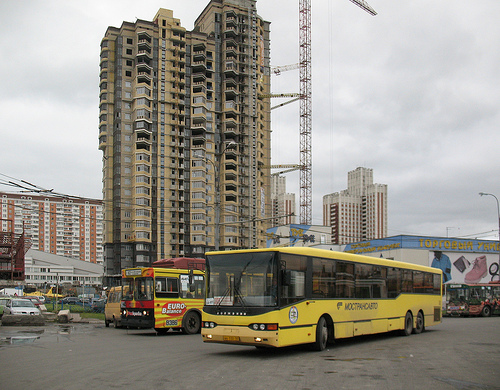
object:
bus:
[201, 247, 443, 351]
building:
[271, 173, 294, 225]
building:
[99, 0, 273, 293]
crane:
[349, 0, 377, 16]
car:
[3, 299, 41, 316]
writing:
[452, 241, 458, 249]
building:
[310, 235, 500, 285]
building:
[0, 189, 108, 293]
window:
[311, 258, 336, 297]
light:
[255, 337, 261, 341]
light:
[207, 334, 212, 338]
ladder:
[250, 9, 258, 251]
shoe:
[464, 255, 487, 284]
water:
[0, 336, 36, 345]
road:
[1, 315, 498, 389]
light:
[479, 192, 488, 196]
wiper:
[215, 288, 230, 310]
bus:
[120, 257, 206, 334]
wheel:
[402, 312, 413, 336]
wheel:
[314, 317, 329, 351]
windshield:
[205, 252, 278, 306]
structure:
[261, 0, 312, 244]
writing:
[348, 302, 352, 309]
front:
[120, 268, 157, 333]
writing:
[162, 308, 166, 314]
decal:
[161, 301, 186, 316]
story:
[99, 75, 270, 95]